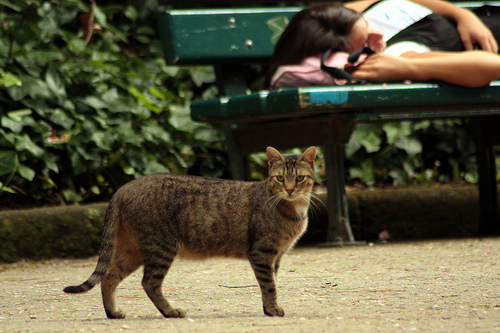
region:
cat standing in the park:
[63, 146, 323, 317]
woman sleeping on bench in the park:
[270, 2, 498, 93]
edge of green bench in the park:
[162, 10, 268, 120]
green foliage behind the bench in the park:
[1, 1, 159, 173]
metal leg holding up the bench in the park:
[326, 115, 359, 245]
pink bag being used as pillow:
[271, 54, 359, 85]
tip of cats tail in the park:
[61, 285, 88, 293]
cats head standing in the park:
[264, 144, 318, 200]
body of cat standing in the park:
[130, 175, 267, 256]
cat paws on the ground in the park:
[104, 304, 287, 318]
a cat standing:
[64, 149, 313, 314]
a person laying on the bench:
[277, 0, 499, 76]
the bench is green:
[164, 16, 246, 55]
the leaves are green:
[20, 50, 169, 167]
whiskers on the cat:
[305, 188, 324, 219]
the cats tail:
[63, 280, 90, 296]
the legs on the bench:
[320, 139, 358, 241]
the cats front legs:
[252, 255, 284, 320]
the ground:
[330, 245, 497, 325]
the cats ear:
[265, 144, 284, 166]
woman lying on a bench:
[285, 9, 420, 71]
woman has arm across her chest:
[414, 0, 487, 66]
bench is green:
[163, 20, 343, 118]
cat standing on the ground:
[119, 155, 303, 305]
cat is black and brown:
[129, 152, 274, 274]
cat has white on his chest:
[298, 219, 311, 254]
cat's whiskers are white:
[265, 183, 326, 209]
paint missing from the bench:
[298, 83, 355, 108]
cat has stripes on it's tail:
[83, 240, 118, 296]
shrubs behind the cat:
[59, 47, 173, 160]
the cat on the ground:
[50, 142, 322, 327]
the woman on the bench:
[249, 2, 477, 81]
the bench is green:
[158, 1, 498, 157]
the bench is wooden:
[161, 5, 490, 252]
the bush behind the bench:
[28, 13, 169, 164]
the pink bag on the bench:
[273, 54, 382, 87]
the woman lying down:
[259, 10, 498, 82]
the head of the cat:
[248, 135, 322, 210]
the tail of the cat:
[63, 208, 119, 298]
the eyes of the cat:
[276, 170, 303, 183]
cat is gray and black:
[28, 119, 328, 323]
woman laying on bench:
[240, 6, 497, 87]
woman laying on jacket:
[251, 31, 358, 93]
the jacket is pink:
[248, 50, 380, 92]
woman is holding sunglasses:
[307, 48, 397, 90]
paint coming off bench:
[303, 86, 351, 115]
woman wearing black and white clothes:
[356, 1, 493, 56]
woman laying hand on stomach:
[445, 6, 499, 66]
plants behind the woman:
[3, 4, 494, 195]